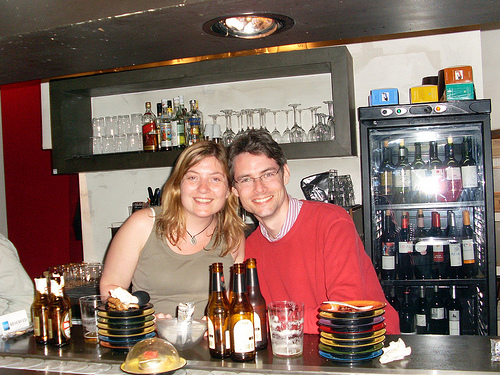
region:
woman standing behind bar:
[135, 145, 227, 330]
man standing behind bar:
[237, 145, 381, 322]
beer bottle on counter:
[199, 259, 233, 361]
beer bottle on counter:
[219, 263, 244, 362]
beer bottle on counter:
[245, 263, 272, 340]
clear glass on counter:
[265, 299, 318, 362]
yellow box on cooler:
[407, 75, 428, 105]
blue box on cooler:
[370, 86, 394, 101]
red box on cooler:
[444, 53, 475, 84]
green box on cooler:
[447, 80, 479, 97]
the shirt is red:
[251, 218, 403, 321]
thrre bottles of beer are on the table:
[188, 248, 273, 369]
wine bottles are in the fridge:
[383, 152, 496, 339]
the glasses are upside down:
[213, 103, 350, 145]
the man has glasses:
[234, 141, 417, 338]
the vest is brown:
[141, 226, 228, 314]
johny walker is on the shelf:
[141, 93, 161, 152]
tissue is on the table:
[378, 333, 420, 370]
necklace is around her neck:
[176, 218, 221, 254]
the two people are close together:
[91, 157, 407, 329]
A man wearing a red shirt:
[225, 127, 406, 334]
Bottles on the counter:
[199, 257, 271, 360]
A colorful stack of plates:
[315, 296, 387, 366]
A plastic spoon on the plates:
[322, 299, 374, 311]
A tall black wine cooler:
[354, 99, 498, 336]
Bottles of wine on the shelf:
[378, 134, 480, 202]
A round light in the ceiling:
[201, 9, 293, 41]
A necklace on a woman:
[169, 214, 218, 245]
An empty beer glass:
[267, 299, 308, 358]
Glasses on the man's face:
[230, 165, 280, 187]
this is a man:
[232, 137, 307, 251]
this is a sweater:
[294, 211, 340, 289]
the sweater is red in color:
[299, 221, 341, 278]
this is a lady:
[145, 139, 228, 256]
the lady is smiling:
[190, 195, 217, 207]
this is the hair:
[218, 209, 240, 249]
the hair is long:
[218, 205, 241, 247]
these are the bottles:
[205, 254, 262, 361]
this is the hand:
[105, 220, 147, 280]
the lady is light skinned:
[115, 230, 137, 257]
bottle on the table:
[235, 258, 256, 365]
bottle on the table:
[209, 255, 231, 355]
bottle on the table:
[235, 250, 272, 348]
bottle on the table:
[49, 273, 71, 343]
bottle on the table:
[30, 283, 51, 345]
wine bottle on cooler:
[451, 201, 476, 268]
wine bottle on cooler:
[445, 210, 468, 277]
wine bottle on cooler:
[422, 201, 450, 276]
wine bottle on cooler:
[397, 208, 413, 270]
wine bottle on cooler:
[378, 208, 395, 274]